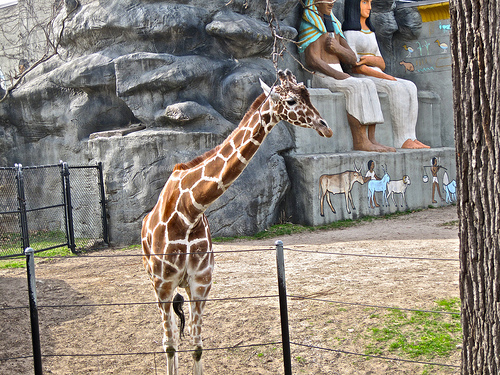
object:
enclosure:
[2, 0, 498, 370]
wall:
[314, 156, 461, 221]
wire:
[24, 249, 284, 259]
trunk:
[447, 8, 500, 326]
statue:
[300, 0, 397, 152]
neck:
[189, 109, 273, 216]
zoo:
[0, 156, 497, 373]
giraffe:
[136, 67, 341, 373]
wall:
[0, 1, 303, 248]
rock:
[207, 13, 297, 66]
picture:
[315, 158, 450, 221]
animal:
[307, 167, 446, 206]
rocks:
[39, 4, 196, 174]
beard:
[324, 15, 336, 33]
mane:
[214, 100, 267, 139]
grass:
[338, 255, 450, 373]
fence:
[0, 161, 462, 373]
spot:
[199, 154, 233, 182]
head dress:
[293, 0, 348, 52]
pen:
[3, 2, 496, 372]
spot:
[165, 217, 188, 243]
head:
[273, 64, 334, 139]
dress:
[294, 4, 344, 54]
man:
[292, 0, 352, 92]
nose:
[309, 110, 339, 145]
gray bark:
[467, 129, 495, 303]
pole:
[228, 226, 327, 361]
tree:
[449, 3, 498, 375]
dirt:
[0, 245, 456, 368]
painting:
[325, 166, 457, 214]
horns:
[271, 63, 293, 85]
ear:
[251, 78, 275, 101]